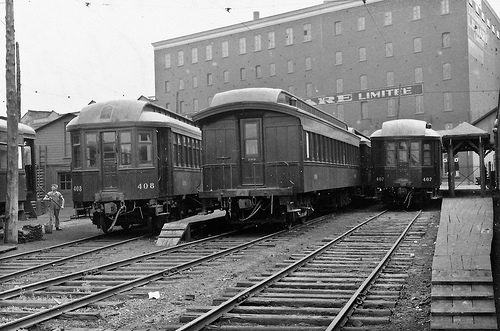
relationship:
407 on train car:
[422, 172, 437, 187] [361, 115, 446, 202]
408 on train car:
[137, 180, 157, 192] [54, 93, 203, 228]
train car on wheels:
[64, 96, 193, 237] [88, 210, 150, 237]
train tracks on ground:
[1, 209, 431, 329] [1, 187, 499, 329]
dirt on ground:
[111, 244, 257, 306] [46, 202, 450, 324]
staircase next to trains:
[432, 195, 499, 329] [189, 74, 379, 230]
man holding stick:
[42, 182, 66, 231] [31, 173, 68, 217]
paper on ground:
[145, 289, 163, 304] [1, 200, 439, 328]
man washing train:
[42, 182, 66, 231] [70, 121, 185, 200]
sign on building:
[296, 81, 425, 106] [146, 21, 482, 155]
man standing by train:
[31, 182, 72, 233] [65, 92, 206, 244]